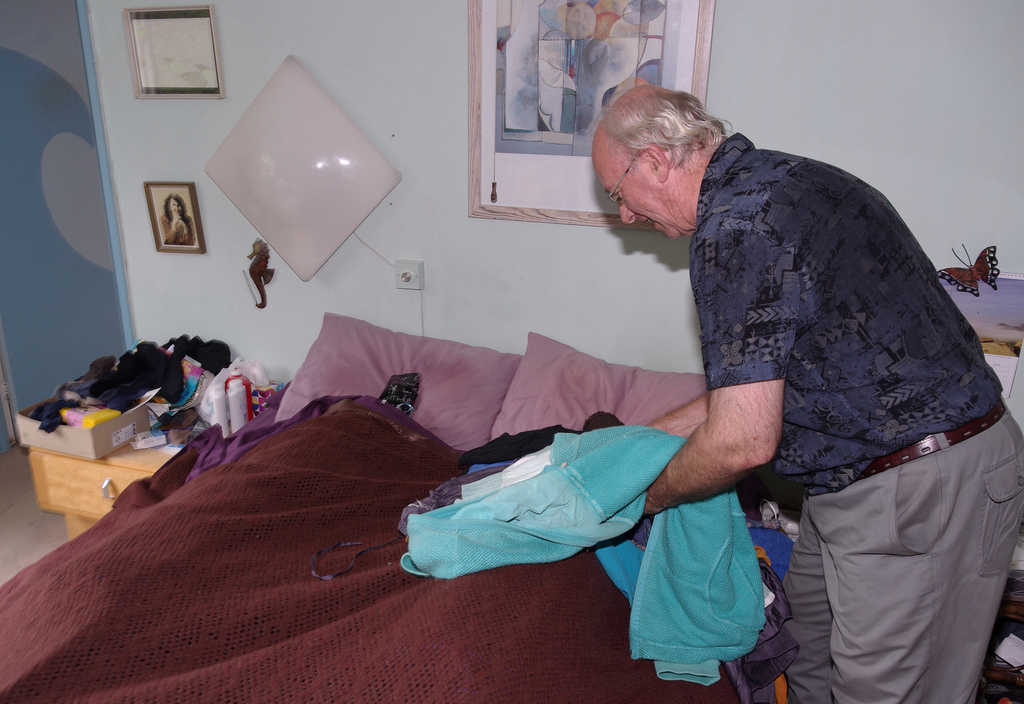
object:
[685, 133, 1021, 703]
clothing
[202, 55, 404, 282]
light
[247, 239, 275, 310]
seahorse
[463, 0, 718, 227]
picture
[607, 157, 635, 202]
glasses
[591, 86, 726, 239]
head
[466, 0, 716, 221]
picture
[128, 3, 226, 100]
picture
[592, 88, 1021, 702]
man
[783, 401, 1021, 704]
pants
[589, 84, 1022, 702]
man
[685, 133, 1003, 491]
shirt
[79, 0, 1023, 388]
wall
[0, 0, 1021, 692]
building